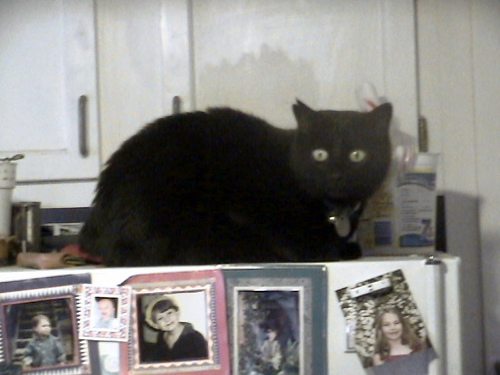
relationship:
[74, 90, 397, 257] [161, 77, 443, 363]
cat looking camera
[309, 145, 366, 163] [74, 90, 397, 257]
eyes of cat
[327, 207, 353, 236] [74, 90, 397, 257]
collar of cat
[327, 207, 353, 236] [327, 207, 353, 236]
collar on collar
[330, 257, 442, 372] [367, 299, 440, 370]
picture of girl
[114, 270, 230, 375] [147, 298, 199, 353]
picture of child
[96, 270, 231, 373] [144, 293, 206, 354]
picture of child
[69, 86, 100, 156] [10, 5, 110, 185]
handle of door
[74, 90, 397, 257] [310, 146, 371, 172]
cat has eyes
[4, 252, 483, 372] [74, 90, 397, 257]
refrigerator under cat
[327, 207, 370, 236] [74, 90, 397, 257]
collar under cat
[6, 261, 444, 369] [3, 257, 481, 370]
photograph on fridge